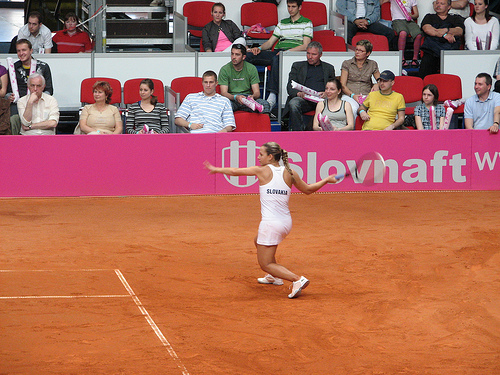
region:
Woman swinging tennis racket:
[202, 140, 339, 297]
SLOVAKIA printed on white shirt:
[264, 186, 292, 198]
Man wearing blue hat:
[357, 68, 409, 133]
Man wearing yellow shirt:
[357, 70, 405, 128]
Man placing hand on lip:
[14, 72, 61, 133]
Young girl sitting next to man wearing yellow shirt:
[412, 83, 442, 127]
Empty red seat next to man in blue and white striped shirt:
[232, 113, 272, 130]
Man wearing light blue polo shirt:
[463, 71, 498, 132]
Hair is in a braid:
[261, 140, 293, 183]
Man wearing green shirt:
[219, 43, 267, 110]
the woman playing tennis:
[183, 135, 399, 322]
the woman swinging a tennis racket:
[194, 129, 393, 287]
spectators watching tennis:
[3, 38, 481, 120]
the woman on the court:
[187, 128, 402, 307]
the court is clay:
[11, 201, 488, 358]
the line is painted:
[136, 303, 192, 373]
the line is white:
[125, 294, 199, 371]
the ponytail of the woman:
[276, 150, 301, 180]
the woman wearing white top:
[241, 160, 298, 217]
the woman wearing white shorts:
[238, 217, 307, 252]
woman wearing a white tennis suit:
[214, 123, 333, 309]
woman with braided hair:
[234, 127, 300, 199]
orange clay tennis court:
[51, 221, 216, 334]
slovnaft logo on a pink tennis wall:
[274, 138, 469, 192]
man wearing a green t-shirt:
[205, 30, 267, 110]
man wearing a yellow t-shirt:
[352, 60, 409, 135]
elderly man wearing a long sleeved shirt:
[16, 61, 64, 142]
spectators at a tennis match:
[66, 1, 443, 129]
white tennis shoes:
[251, 258, 320, 315]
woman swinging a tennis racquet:
[211, 117, 381, 287]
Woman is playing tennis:
[187, 126, 402, 306]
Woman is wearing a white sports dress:
[238, 150, 312, 252]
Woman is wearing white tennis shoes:
[241, 263, 323, 304]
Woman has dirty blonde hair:
[256, 133, 300, 193]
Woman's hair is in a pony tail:
[251, 133, 302, 191]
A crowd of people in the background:
[0, 0, 496, 130]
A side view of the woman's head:
[250, 136, 296, 171]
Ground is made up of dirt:
[2, 195, 497, 365]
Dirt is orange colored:
[5, 198, 497, 369]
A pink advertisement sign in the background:
[1, 133, 499, 195]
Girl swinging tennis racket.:
[199, 140, 388, 305]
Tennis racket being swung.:
[324, 146, 387, 187]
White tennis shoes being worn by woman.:
[256, 272, 313, 301]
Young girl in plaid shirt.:
[413, 82, 450, 132]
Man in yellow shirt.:
[358, 67, 407, 134]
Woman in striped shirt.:
[125, 79, 170, 135]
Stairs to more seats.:
[99, 0, 174, 49]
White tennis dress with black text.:
[254, 164, 295, 249]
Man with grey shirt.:
[464, 70, 499, 139]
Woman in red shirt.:
[51, 12, 93, 54]